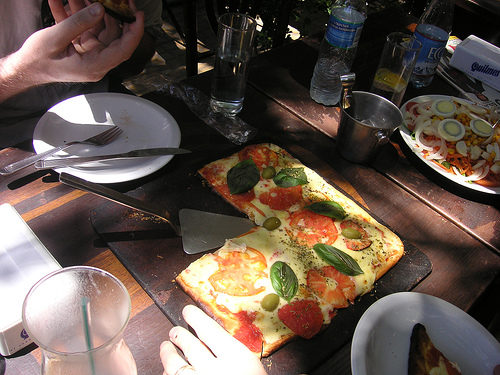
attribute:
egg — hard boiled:
[441, 118, 464, 139]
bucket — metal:
[335, 91, 402, 161]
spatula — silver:
[179, 211, 260, 258]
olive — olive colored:
[262, 293, 285, 307]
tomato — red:
[288, 209, 346, 249]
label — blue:
[322, 16, 358, 48]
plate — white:
[348, 291, 498, 371]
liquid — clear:
[208, 54, 244, 108]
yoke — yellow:
[444, 122, 458, 134]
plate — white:
[35, 93, 180, 189]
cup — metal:
[332, 87, 397, 161]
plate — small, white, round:
[30, 89, 183, 187]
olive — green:
[262, 289, 284, 310]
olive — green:
[260, 208, 284, 228]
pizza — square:
[168, 142, 408, 362]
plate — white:
[399, 90, 499, 193]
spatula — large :
[50, 159, 266, 253]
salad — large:
[399, 91, 485, 189]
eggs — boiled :
[430, 91, 484, 143]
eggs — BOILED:
[424, 94, 493, 160]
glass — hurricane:
[1, 247, 141, 370]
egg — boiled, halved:
[428, 96, 461, 117]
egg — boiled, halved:
[438, 116, 468, 142]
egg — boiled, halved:
[468, 116, 498, 139]